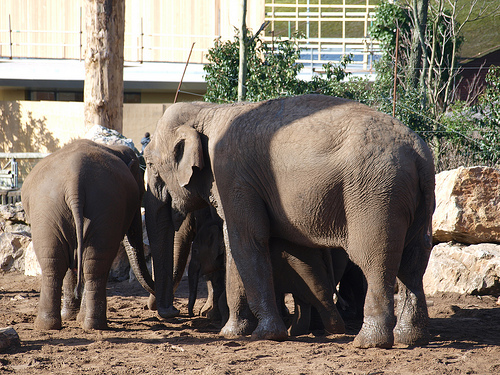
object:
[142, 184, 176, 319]
trunk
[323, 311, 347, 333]
left foot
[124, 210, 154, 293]
trunk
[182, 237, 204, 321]
trunk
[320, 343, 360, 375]
ground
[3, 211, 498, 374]
space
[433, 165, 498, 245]
rock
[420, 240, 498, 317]
rock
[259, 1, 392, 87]
building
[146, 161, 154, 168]
eye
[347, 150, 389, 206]
lines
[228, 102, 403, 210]
skin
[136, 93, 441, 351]
elephant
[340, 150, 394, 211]
ketchup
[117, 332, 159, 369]
dirt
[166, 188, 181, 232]
mouth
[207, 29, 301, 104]
tree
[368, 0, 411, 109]
tree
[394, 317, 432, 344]
foot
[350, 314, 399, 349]
foot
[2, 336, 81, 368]
ground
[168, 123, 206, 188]
ear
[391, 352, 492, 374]
ground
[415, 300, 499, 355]
shadow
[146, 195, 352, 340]
elephant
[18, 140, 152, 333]
elephant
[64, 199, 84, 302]
tail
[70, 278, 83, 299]
hair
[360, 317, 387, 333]
marks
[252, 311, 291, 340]
foot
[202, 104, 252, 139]
skin